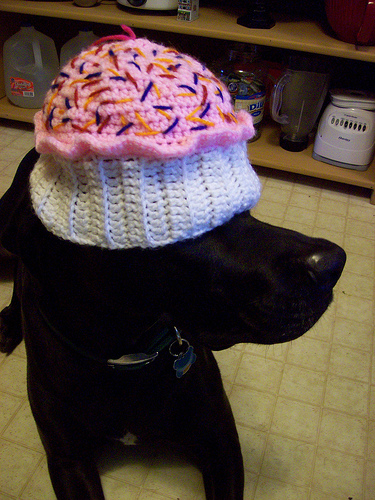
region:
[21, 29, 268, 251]
crocheted hat on a dog's hat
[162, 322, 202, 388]
blue metal tag on a dog's collar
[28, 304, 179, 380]
dog's collar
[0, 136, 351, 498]
black dog sitting on the floor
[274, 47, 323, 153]
blender container on the bottom shelf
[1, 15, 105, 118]
two gallons of water on the bottom shelf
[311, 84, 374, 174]
white blender base on the bottom shelf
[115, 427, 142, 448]
white spot of fur on dog's chest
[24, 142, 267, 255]
bottom of cap covering dog's eyes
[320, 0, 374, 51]
red container on top shelf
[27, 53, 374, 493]
black dog with knitter cupcake on head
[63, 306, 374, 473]
tile floor under black dog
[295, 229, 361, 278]
shiny black nose on dog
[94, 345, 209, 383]
blue collar on dog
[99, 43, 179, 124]
stitched sprinkles on dog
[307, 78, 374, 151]
WHITE BLENDER UNDER CABINET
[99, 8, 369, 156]
TAN SHELVES BEHIND DOG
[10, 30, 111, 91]
GALLONS OF WATER ON LEFT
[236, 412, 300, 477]
SHADOW OF DOG ON TILE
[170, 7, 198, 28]
SMALL GREEN OBJECT ON SHELF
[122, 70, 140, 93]
red yarn in pink yarn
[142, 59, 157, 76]
red yarn in pink yarn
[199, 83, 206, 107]
red yarn in pink yarn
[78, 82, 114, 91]
red yarn in pink yarn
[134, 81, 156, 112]
Blue yarn in pink yarn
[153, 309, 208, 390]
Blue dog collar on dog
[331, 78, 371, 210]
White belnder on shelf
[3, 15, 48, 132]
Clear water jug on shelf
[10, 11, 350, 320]
Very ugly crochet hat on dog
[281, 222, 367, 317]
Black nose of a dog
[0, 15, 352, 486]
black dog wearing a white and pink hat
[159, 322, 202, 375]
tags on collar of black dog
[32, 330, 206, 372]
collar with tags on a black dog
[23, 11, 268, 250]
white, red, blue and pink knitted hat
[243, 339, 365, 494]
yellow vinyl flooring under black dog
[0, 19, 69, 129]
plastic jug of water on wooden shelf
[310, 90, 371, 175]
bent white can on a wooden shelf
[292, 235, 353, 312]
black shiny nose on a black dog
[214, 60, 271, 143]
glass bottle with label on a wooden shelf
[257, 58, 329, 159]
plastic pitcher on a wooden shelf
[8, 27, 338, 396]
Black dog wearing beanie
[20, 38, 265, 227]
Pink and white knitted beanie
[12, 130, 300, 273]
Dog's eyes covered by hat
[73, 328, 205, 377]
Dog's collar and id tag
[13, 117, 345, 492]
Dog sitting on tan floor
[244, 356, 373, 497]
Tiled tan floor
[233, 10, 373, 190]
Light tan wooden shelving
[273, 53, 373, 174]
Blender sitting on shelf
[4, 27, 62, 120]
Gallon water bottles on shelf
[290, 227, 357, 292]
Black nose of dog